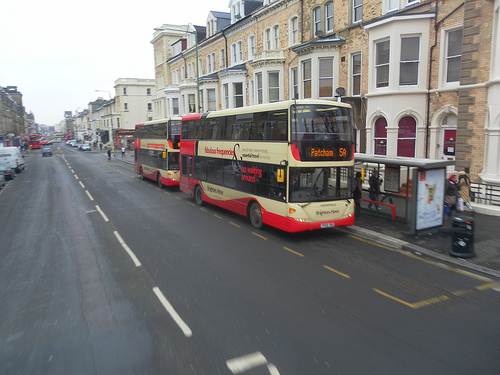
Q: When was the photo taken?
A: Daytime.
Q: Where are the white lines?
A: Street.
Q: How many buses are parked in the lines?
A: Two.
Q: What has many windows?
A: Buildings.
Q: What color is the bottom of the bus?
A: Red.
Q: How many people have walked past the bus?
A: Two.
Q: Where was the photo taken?
A: On a city street.